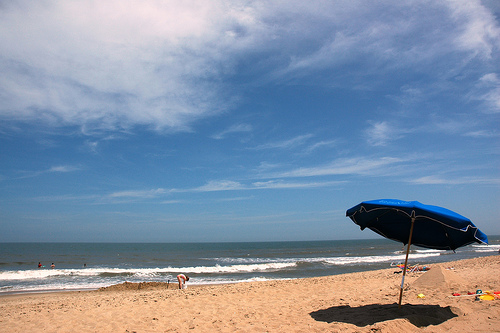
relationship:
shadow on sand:
[305, 295, 463, 330] [274, 311, 327, 333]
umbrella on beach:
[345, 198, 486, 311] [85, 284, 237, 329]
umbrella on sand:
[341, 195, 479, 313] [223, 295, 299, 320]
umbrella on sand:
[345, 198, 486, 311] [169, 293, 269, 318]